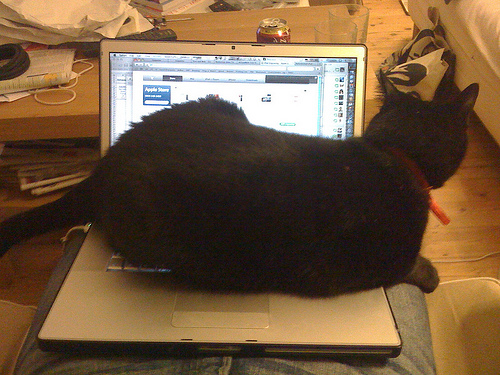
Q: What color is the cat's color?
A: Red.